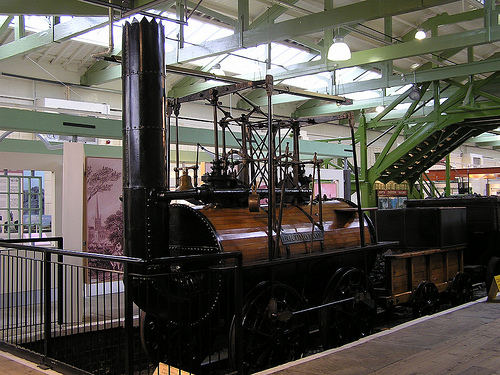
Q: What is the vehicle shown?
A: Train.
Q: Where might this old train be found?
A: Museum.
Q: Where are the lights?
A: On ceiling.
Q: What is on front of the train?
A: Chimney.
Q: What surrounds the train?
A: Black fence.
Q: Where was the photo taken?
A: Museum.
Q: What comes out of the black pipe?
A: Steam.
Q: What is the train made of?
A: Metal and wood.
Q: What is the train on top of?
A: Tracks.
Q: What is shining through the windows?
A: Sunlight.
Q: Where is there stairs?
A: Behind train.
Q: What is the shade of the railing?
A: Green.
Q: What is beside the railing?
A: Steps.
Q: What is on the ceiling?
A: Green beams.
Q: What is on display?
A: Antique train.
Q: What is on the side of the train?
A: Wood.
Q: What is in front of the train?
A: Black railing.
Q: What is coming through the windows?
A: Skylight.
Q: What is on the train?
A: Black pipe.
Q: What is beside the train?
A: Display.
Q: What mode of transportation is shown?
A: Train.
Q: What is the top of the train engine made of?
A: Wood.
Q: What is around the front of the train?
A: Railing.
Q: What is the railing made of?
A: Metal.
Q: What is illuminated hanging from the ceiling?
A: Lights.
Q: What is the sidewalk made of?
A: Concrete.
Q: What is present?
A: A train.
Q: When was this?
A: Daytime.